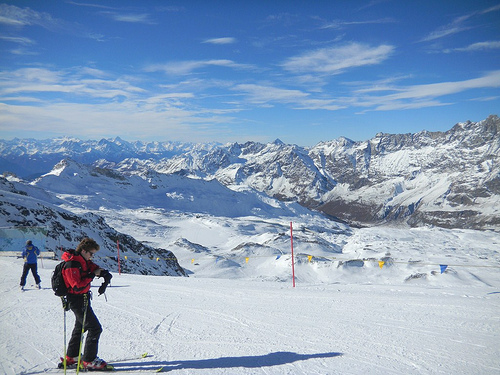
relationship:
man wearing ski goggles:
[51, 238, 115, 372] [80, 249, 94, 259]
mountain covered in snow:
[10, 117, 495, 287] [0, 137, 500, 373]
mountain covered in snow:
[0, 114, 500, 276] [187, 284, 473, 366]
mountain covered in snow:
[0, 114, 500, 276] [303, 226, 484, 340]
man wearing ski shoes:
[51, 238, 115, 372] [57, 347, 163, 374]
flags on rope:
[125, 250, 392, 279] [285, 252, 481, 271]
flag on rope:
[439, 262, 449, 273] [80, 252, 498, 269]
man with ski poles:
[51, 238, 115, 372] [47, 283, 118, 371]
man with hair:
[56, 229, 115, 314] [75, 235, 102, 252]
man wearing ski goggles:
[51, 238, 115, 372] [87, 250, 95, 257]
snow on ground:
[324, 304, 452, 359] [193, 280, 461, 357]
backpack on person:
[43, 252, 73, 300] [45, 238, 130, 368]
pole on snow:
[290, 221, 296, 287] [3, 165, 499, 373]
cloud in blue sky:
[0, 0, 499, 142] [0, 0, 498, 154]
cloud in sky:
[283, 37, 393, 77] [0, 3, 496, 150]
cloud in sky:
[0, 0, 499, 142] [9, 2, 480, 142]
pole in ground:
[286, 215, 300, 285] [283, 280, 307, 299]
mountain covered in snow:
[10, 117, 495, 287] [2, 114, 492, 373]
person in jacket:
[13, 236, 45, 291] [22, 248, 40, 263]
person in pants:
[13, 236, 45, 291] [19, 264, 44, 285]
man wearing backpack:
[51, 238, 115, 372] [51, 258, 94, 304]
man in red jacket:
[51, 238, 115, 372] [61, 248, 105, 294]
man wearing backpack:
[51, 238, 115, 372] [52, 257, 93, 298]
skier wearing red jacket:
[69, 255, 100, 285] [47, 250, 107, 300]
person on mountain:
[16, 239, 41, 290] [14, 167, 462, 354]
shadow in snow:
[109, 345, 343, 373] [12, 273, 489, 365]